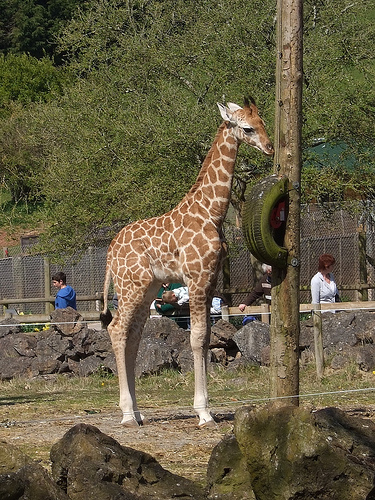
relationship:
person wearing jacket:
[233, 263, 272, 316] [239, 274, 272, 305]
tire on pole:
[240, 176, 288, 266] [268, 0, 300, 404]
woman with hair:
[310, 254, 337, 316] [315, 243, 336, 268]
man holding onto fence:
[255, 259, 284, 321] [3, 296, 368, 329]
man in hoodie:
[52, 271, 78, 311] [55, 284, 78, 311]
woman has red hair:
[310, 254, 337, 316] [314, 252, 337, 272]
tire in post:
[240, 176, 288, 266] [264, 0, 305, 406]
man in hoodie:
[45, 260, 78, 316] [51, 279, 81, 314]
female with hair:
[301, 250, 347, 317] [301, 247, 357, 272]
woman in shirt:
[309, 253, 337, 302] [306, 269, 337, 300]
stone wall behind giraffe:
[3, 310, 104, 374] [90, 96, 281, 437]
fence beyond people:
[1, 213, 112, 319] [45, 228, 346, 344]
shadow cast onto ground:
[154, 403, 368, 420] [0, 360, 353, 493]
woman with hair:
[310, 254, 337, 316] [319, 254, 338, 271]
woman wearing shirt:
[309, 253, 337, 302] [309, 272, 339, 303]